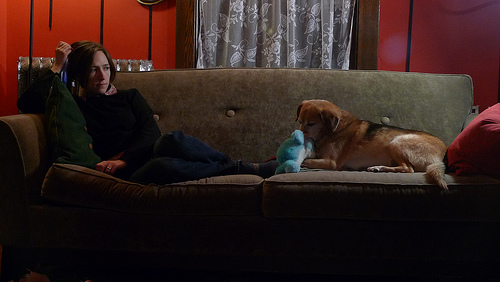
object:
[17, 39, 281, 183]
woman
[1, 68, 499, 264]
couch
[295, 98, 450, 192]
dog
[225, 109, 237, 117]
button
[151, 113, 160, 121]
button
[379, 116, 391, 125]
button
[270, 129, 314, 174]
toy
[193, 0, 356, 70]
curtains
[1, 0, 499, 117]
walls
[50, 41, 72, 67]
right hand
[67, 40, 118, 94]
head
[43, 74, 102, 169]
green pillow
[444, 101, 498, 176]
red pillow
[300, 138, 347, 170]
leg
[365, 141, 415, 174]
leg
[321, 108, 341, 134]
ear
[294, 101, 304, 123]
ear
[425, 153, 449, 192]
tail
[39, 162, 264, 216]
cushion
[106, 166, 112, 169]
ring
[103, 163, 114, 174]
finger